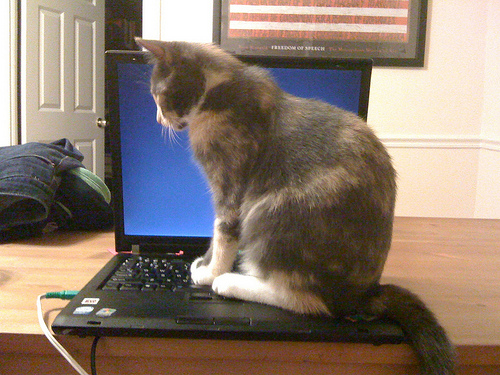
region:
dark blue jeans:
[0, 137, 95, 234]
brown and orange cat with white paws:
[135, 34, 434, 316]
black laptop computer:
[53, 45, 400, 345]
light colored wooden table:
[2, 142, 496, 371]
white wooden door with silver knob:
[12, 2, 116, 207]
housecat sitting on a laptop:
[50, 33, 490, 370]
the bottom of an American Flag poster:
[209, 1, 431, 68]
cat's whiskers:
[157, 115, 188, 154]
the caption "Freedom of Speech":
[266, 40, 340, 60]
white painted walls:
[145, 2, 497, 220]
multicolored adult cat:
[134, 34, 456, 372]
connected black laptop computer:
[37, 47, 404, 373]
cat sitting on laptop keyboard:
[52, 37, 458, 372]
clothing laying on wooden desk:
[1, 136, 115, 244]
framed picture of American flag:
[214, 2, 426, 65]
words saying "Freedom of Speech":
[269, 40, 326, 54]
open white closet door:
[20, 0, 107, 184]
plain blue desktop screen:
[117, 60, 358, 233]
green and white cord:
[34, 289, 87, 374]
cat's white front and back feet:
[193, 235, 332, 318]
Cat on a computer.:
[130, 32, 420, 317]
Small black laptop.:
[47, 45, 427, 327]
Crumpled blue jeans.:
[0, 140, 110, 235]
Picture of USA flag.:
[217, 0, 457, 40]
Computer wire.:
[35, 285, 91, 372]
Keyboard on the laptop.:
[123, 255, 183, 295]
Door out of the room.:
[18, 1, 108, 141]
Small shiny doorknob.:
[87, 110, 107, 132]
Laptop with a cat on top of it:
[102, 45, 467, 351]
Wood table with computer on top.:
[1, 215, 497, 372]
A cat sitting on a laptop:
[132, 35, 457, 372]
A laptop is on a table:
[48, 48, 408, 345]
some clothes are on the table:
[2, 137, 112, 244]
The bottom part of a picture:
[211, 3, 428, 68]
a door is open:
[19, 2, 106, 180]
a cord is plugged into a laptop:
[36, 290, 89, 371]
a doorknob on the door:
[96, 116, 109, 129]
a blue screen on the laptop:
[104, 48, 374, 251]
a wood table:
[2, 216, 497, 371]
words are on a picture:
[270, 42, 327, 52]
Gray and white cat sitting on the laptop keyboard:
[63, 36, 409, 337]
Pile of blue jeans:
[6, 134, 108, 251]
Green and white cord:
[33, 279, 81, 310]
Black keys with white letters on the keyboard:
[124, 255, 181, 294]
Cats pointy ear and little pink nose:
[136, 32, 211, 128]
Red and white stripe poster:
[221, 0, 423, 57]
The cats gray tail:
[369, 259, 459, 366]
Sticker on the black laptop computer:
[71, 295, 121, 321]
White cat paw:
[212, 265, 320, 307]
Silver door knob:
[89, 105, 114, 135]